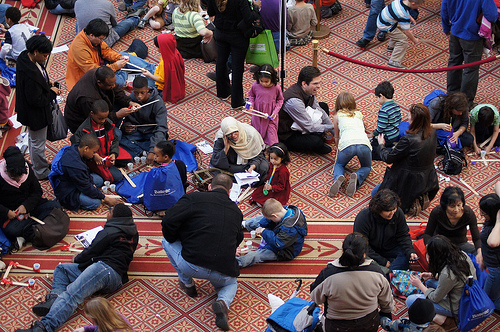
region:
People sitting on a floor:
[1, 0, 498, 330]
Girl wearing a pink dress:
[241, 62, 285, 148]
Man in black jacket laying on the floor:
[17, 203, 139, 330]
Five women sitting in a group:
[307, 186, 498, 330]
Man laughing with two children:
[280, 65, 405, 197]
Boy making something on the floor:
[459, 101, 499, 166]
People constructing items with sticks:
[0, 0, 496, 330]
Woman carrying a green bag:
[198, 0, 280, 108]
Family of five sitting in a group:
[49, 63, 191, 218]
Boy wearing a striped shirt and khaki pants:
[376, 0, 422, 70]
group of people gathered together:
[0, 0, 499, 331]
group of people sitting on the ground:
[1, 0, 498, 330]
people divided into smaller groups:
[0, 0, 498, 329]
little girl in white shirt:
[330, 90, 372, 195]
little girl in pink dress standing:
[245, 58, 280, 140]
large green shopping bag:
[247, 28, 278, 65]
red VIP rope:
[310, 40, 499, 88]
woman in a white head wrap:
[212, 117, 267, 179]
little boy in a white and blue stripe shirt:
[374, 0, 421, 65]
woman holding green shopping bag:
[198, 0, 276, 107]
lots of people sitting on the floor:
[18, 19, 499, 310]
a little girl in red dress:
[241, 145, 311, 202]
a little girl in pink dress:
[231, 75, 300, 157]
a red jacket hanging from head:
[153, 21, 195, 109]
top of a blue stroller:
[253, 271, 310, 328]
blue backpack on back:
[436, 272, 490, 329]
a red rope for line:
[298, 32, 498, 82]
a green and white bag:
[214, 18, 292, 88]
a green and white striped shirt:
[172, 9, 211, 51]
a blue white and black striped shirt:
[366, 3, 416, 42]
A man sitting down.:
[280, 65, 337, 156]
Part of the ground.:
[143, 295, 173, 325]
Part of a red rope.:
[342, 46, 374, 71]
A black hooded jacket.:
[73, 217, 134, 278]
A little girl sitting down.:
[252, 142, 289, 206]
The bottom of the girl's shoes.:
[327, 173, 357, 197]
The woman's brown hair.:
[408, 101, 431, 135]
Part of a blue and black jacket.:
[276, 230, 300, 247]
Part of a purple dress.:
[258, 95, 273, 105]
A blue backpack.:
[456, 280, 493, 327]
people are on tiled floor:
[26, 20, 443, 308]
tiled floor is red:
[169, 84, 234, 153]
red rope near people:
[342, 50, 493, 95]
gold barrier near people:
[297, 39, 338, 101]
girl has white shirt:
[322, 99, 364, 146]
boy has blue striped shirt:
[365, 99, 390, 134]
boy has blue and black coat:
[252, 207, 305, 253]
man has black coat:
[163, 176, 245, 273]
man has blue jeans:
[154, 246, 226, 301]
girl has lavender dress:
[244, 64, 283, 151]